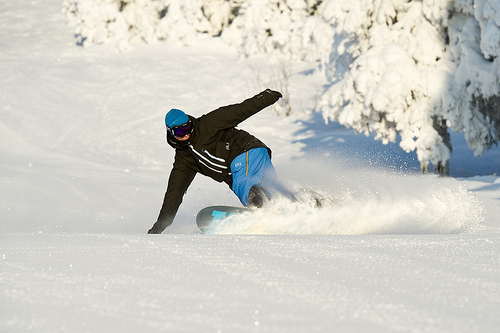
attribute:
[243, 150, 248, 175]
stripe — orange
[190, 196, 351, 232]
board — black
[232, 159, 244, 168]
symbol — white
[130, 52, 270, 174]
jacket — white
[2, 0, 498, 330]
snow — white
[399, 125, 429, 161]
snow — white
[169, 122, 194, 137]
goggles — purple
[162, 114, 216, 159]
goggles — black